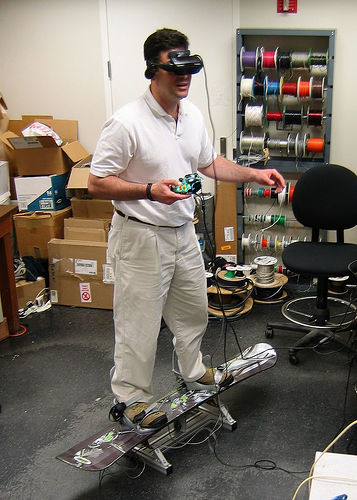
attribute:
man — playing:
[88, 26, 284, 434]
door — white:
[104, 2, 237, 195]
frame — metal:
[128, 391, 237, 479]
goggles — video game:
[144, 47, 223, 89]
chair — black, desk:
[265, 163, 356, 363]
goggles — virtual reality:
[141, 49, 214, 77]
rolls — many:
[238, 40, 328, 283]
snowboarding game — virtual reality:
[53, 341, 274, 482]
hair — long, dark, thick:
[140, 25, 200, 74]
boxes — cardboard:
[1, 99, 110, 315]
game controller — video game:
[166, 171, 202, 196]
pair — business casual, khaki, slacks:
[97, 210, 236, 410]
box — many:
[2, 110, 86, 170]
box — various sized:
[47, 236, 119, 311]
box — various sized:
[61, 214, 114, 242]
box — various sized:
[69, 153, 109, 200]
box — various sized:
[0, 118, 92, 178]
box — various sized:
[12, 173, 72, 213]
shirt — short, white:
[46, 83, 241, 226]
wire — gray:
[298, 54, 307, 59]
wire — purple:
[244, 49, 251, 61]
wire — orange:
[301, 81, 308, 95]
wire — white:
[248, 107, 259, 125]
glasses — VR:
[157, 55, 208, 75]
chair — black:
[266, 155, 345, 364]